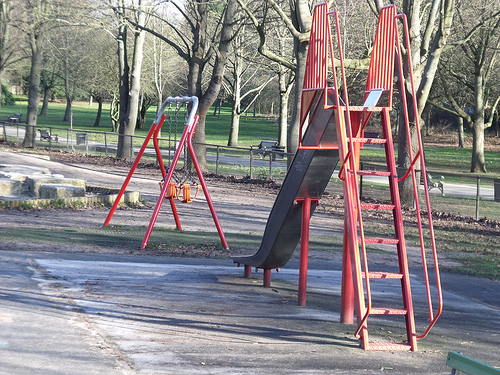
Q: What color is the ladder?
A: Red.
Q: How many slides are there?
A: 1.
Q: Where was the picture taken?
A: At a playground.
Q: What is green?
A: Grass.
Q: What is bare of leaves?
A: Trees.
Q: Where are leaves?
A: On the ground.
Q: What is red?
A: Ladder of slide.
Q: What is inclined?
A: The slide.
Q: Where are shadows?
A: On the ground.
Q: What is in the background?
A: Trees.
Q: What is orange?
A: Swings.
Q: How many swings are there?
A: Two.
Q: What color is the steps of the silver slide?
A: Red.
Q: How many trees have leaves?
A: None.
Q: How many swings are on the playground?
A: Two.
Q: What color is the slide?
A: Silver.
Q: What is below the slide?
A: Concrete.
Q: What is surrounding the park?
A: Fence.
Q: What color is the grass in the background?
A: Green.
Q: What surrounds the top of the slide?
A: Railing.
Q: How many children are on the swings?
A: None.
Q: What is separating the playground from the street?
A: A fence.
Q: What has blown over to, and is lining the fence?
A: Leaves.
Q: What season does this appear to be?
A: Fall.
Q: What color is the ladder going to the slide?
A: Red.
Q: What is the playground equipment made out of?
A: Metal.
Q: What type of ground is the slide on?
A: Concrete.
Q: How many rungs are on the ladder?
A: 6.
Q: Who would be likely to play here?
A: Children.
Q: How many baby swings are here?
A: 2.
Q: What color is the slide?
A: Red.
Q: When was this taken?
A: Daytime.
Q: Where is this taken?
A: A playground.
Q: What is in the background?
A: Trees.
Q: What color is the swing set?
A: Red.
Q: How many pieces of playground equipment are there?
A: Two.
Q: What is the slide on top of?
A: Pavement.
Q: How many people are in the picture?
A: None.